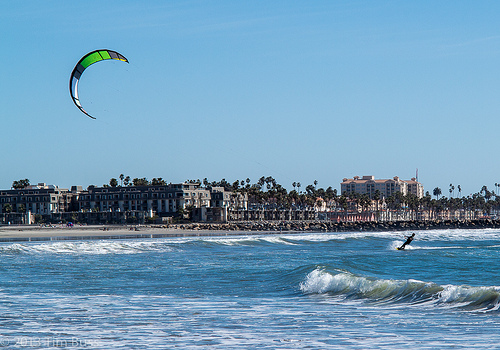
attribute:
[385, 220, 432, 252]
wakeboarder — black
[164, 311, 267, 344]
ripple — on water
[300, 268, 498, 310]
white wave — on water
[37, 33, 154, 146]
parachute — next to water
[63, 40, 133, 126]
sail — above water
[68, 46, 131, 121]
kite — flying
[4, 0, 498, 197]
sky — above water, clear, blue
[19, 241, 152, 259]
foam — white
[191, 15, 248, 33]
white cloud — above water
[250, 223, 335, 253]
wave — on water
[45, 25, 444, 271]
parachute — next to water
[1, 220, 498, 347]
ocean — blue, is moving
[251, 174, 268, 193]
trees — near beach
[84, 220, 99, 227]
patch — brown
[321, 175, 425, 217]
red roof — is red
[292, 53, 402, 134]
blue sky — above water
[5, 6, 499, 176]
sky — blue, clear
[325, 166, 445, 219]
building — tall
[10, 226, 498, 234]
line — next to water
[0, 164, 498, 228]
city — next to water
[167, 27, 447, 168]
sky — above water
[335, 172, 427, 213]
hotel — next to water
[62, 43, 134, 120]
kite — in air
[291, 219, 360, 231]
rocks — by sand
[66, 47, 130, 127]
sail — green